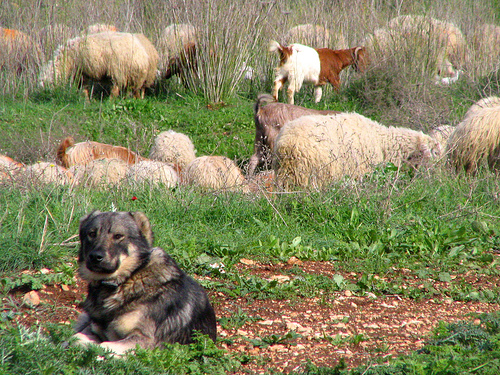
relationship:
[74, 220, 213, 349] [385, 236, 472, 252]
sheep dog on grass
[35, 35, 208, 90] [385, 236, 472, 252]
sheep in grass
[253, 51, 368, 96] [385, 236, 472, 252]
goat in grass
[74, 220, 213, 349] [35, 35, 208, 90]
sheep dog guarding sheep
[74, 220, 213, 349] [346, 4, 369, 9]
sheep dog in daylight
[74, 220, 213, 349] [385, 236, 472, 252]
sheep dog resting in grass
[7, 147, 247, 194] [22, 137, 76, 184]
sheep in a row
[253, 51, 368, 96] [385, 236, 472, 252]
goat eating grass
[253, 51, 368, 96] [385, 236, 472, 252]
goat standing in grass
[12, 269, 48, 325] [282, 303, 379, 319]
rock on dirt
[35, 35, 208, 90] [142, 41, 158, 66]
sheep has short tail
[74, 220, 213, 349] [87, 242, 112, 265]
sheep dog has black nose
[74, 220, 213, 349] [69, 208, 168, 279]
sheep dog has head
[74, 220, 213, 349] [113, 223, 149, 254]
sheep dog has eye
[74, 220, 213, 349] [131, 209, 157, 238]
sheep dog has ear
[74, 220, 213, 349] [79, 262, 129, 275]
sheep dog has mouth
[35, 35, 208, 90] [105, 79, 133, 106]
sheep has leg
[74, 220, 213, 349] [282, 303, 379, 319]
sheep dog on dirt